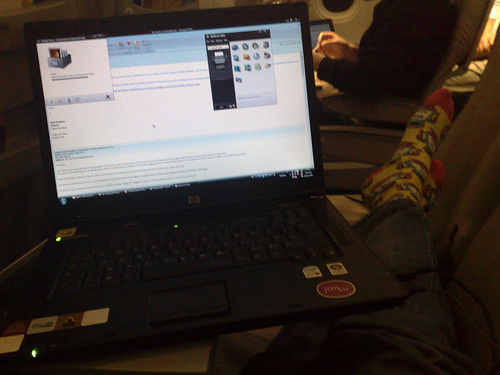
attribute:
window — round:
[321, 0, 353, 15]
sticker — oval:
[297, 253, 367, 317]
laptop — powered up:
[14, 5, 406, 368]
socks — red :
[360, 88, 442, 207]